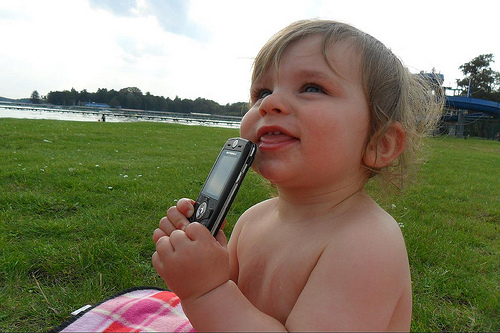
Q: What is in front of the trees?
A: Water.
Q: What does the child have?
A: Pink blanket.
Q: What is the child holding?
A: Cell phone.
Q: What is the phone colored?
A: Silver and black.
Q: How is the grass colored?
A: Green.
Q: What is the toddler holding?
A: Cell phone.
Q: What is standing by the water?
A: A man.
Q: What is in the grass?
A: Blanket.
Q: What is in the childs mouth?
A: A phone.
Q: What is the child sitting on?
A: A blanket.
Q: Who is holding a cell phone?
A: A baby.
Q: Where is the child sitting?
A: In the grass.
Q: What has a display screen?
A: Cell phone.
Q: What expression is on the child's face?
A: A smile.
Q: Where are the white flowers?
A: In the grass.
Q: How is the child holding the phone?
A: With both hands.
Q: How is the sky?
A: Cloudy.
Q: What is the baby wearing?
A: Nothing.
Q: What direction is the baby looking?
A: Up.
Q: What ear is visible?
A: Left.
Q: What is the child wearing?
A: Not wearing any shirt.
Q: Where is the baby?
A: Park.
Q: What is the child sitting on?
A: Blanket.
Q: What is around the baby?
A: Grass.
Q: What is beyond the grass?
A: Water.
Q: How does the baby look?
A: Happy.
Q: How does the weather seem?
A: Overcast.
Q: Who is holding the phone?
A: The baby.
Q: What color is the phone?
A: It's black.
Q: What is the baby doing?
A: Just smiling.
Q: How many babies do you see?
A: Only one.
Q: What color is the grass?
A: Dark green.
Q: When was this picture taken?
A: In the daytime.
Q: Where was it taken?
A: On the grass.